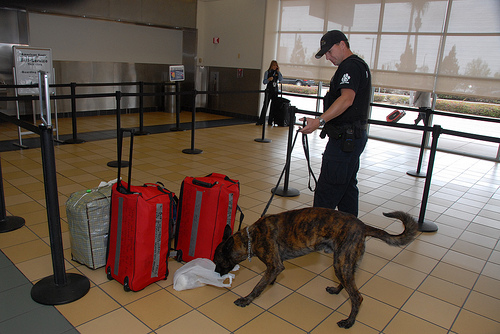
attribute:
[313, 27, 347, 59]
baseball cap — black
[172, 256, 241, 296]
bag — plastic, white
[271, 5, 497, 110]
blinds — halfway drawn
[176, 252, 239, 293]
bag — plastic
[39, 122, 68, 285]
pole — black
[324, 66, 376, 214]
outfit — black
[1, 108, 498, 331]
floor — tan colored, tile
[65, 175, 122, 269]
bag — clear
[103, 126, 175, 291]
bag — clear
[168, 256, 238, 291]
bag — clear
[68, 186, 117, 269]
luggage — gray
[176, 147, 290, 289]
suitcase — red, gray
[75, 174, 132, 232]
colored bag — silver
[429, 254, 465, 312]
colored tiles — tan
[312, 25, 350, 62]
cap — black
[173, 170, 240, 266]
bag — clear, identical, red, gray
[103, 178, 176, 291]
bag — identical, red, gray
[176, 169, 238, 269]
luggage — red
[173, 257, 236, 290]
bag — white, plastic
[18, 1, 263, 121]
wall — stainless steel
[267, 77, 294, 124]
suitcase — dark, large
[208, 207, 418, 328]
dog — dark brown, black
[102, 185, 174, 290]
luggage — red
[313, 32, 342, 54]
cap — black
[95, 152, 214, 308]
bag — gray, metallic, duffle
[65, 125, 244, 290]
suitcases — red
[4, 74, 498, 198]
divider rope — black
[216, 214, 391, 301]
dog — black, brown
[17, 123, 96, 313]
pole — black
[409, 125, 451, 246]
pole — black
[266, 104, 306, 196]
pole — black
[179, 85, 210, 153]
pole — black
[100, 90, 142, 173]
pole — black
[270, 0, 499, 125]
window — glass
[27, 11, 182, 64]
white wall — long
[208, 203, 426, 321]
police dog — black, brown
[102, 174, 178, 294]
luggage — red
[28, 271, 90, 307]
base — round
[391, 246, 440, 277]
tile — tan, grey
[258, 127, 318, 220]
leash — black, long